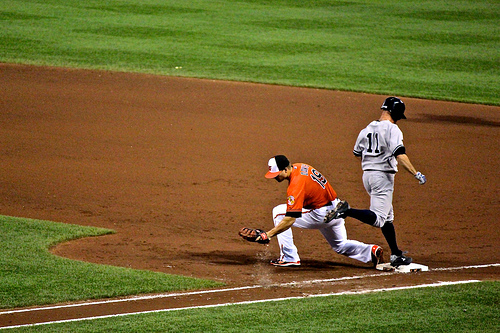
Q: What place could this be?
A: It is a field.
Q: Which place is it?
A: It is a field.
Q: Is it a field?
A: Yes, it is a field.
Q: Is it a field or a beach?
A: It is a field.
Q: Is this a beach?
A: No, it is a field.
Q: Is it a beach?
A: No, it is a field.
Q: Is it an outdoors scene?
A: Yes, it is outdoors.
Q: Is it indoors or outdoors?
A: It is outdoors.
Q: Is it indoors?
A: No, it is outdoors.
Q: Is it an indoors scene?
A: No, it is outdoors.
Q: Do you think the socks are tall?
A: Yes, the socks are tall.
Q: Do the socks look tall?
A: Yes, the socks are tall.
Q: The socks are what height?
A: The socks are tall.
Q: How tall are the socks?
A: The socks are tall.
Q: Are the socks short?
A: No, the socks are tall.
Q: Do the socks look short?
A: No, the socks are tall.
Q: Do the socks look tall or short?
A: The socks are tall.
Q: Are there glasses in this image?
A: No, there are no glasses.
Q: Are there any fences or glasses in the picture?
A: No, there are no glasses or fences.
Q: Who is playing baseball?
A: The man is playing baseball.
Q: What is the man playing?
A: The man is playing baseball.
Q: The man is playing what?
A: The man is playing baseball.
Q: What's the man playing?
A: The man is playing baseball.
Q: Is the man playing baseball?
A: Yes, the man is playing baseball.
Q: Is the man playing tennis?
A: No, the man is playing baseball.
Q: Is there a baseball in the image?
A: Yes, there is a baseball.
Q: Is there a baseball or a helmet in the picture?
A: Yes, there is a baseball.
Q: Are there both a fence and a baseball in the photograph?
A: No, there is a baseball but no fences.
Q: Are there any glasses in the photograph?
A: No, there are no glasses.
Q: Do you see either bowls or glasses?
A: No, there are no glasses or bowls.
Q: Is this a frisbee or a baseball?
A: This is a baseball.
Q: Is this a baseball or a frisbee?
A: This is a baseball.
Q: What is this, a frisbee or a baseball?
A: This is a baseball.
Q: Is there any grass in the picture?
A: Yes, there is grass.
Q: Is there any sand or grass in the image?
A: Yes, there is grass.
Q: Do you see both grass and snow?
A: No, there is grass but no snow.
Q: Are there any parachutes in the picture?
A: No, there are no parachutes.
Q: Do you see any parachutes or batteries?
A: No, there are no parachutes or batteries.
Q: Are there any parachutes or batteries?
A: No, there are no parachutes or batteries.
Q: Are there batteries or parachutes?
A: No, there are no parachutes or batteries.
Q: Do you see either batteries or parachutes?
A: No, there are no parachutes or batteries.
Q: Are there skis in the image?
A: No, there are no skis.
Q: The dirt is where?
A: The dirt is on the field.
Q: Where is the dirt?
A: The dirt is on the field.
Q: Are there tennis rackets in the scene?
A: No, there are no tennis rackets.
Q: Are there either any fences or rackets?
A: No, there are no rackets or fences.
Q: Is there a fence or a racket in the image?
A: No, there are no rackets or fences.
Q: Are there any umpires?
A: No, there are no umpires.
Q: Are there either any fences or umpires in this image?
A: No, there are no umpires or fences.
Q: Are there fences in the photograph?
A: No, there are no fences.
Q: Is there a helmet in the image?
A: Yes, there is a helmet.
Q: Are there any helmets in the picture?
A: Yes, there is a helmet.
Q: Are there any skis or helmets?
A: Yes, there is a helmet.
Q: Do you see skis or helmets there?
A: Yes, there is a helmet.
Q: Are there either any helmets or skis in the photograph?
A: Yes, there is a helmet.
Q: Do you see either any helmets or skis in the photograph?
A: Yes, there is a helmet.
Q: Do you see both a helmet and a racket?
A: No, there is a helmet but no rackets.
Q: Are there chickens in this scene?
A: No, there are no chickens.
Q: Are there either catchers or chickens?
A: No, there are no chickens or catchers.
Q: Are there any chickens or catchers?
A: No, there are no chickens or catchers.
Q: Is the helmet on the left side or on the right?
A: The helmet is on the right of the image.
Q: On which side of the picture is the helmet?
A: The helmet is on the right of the image.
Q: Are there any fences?
A: No, there are no fences.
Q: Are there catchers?
A: No, there are no catchers.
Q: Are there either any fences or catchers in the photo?
A: No, there are no catchers or fences.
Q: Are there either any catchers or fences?
A: No, there are no catchers or fences.